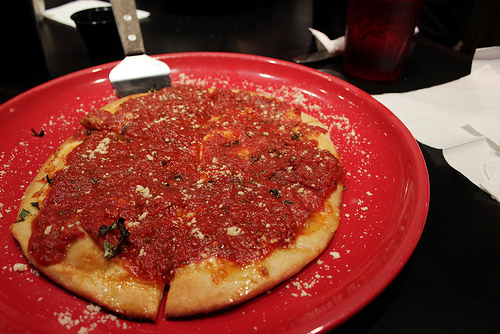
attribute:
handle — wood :
[105, 2, 155, 61]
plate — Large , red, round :
[7, 50, 436, 327]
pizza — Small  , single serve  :
[35, 65, 377, 329]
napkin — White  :
[369, 43, 494, 192]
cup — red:
[337, 0, 447, 116]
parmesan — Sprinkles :
[327, 97, 402, 270]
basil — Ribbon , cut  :
[101, 213, 132, 268]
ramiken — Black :
[72, 6, 142, 82]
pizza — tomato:
[14, 82, 354, 308]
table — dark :
[290, 33, 498, 333]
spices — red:
[103, 133, 204, 203]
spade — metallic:
[111, 51, 178, 107]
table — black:
[10, 54, 438, 289]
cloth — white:
[358, 52, 498, 233]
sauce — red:
[74, 88, 313, 258]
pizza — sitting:
[18, 84, 348, 334]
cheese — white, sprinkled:
[224, 221, 248, 240]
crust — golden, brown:
[12, 228, 152, 334]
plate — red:
[3, 105, 452, 322]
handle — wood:
[120, 103, 149, 120]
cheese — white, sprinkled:
[184, 214, 203, 238]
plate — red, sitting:
[3, 64, 450, 334]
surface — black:
[9, 100, 491, 334]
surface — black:
[6, 66, 493, 326]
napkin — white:
[360, 107, 499, 235]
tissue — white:
[365, 68, 498, 233]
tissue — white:
[370, 50, 499, 250]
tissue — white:
[342, 59, 497, 229]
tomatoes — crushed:
[17, 212, 76, 282]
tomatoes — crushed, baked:
[21, 203, 68, 263]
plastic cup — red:
[335, 1, 422, 82]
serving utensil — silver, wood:
[102, 1, 179, 93]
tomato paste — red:
[24, 86, 342, 291]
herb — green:
[94, 214, 138, 266]